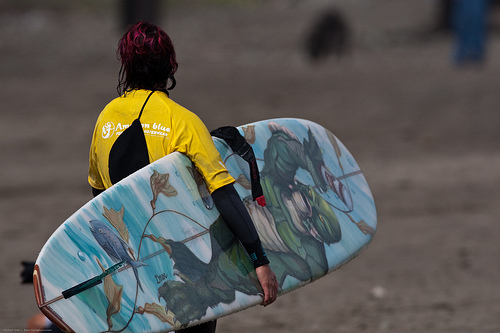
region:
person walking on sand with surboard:
[8, 20, 389, 332]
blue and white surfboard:
[9, 112, 396, 332]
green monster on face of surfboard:
[155, 122, 363, 329]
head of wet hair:
[101, 23, 193, 97]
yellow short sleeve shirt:
[80, 83, 237, 204]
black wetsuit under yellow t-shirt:
[78, 157, 273, 331]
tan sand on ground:
[5, 8, 491, 322]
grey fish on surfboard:
[83, 213, 155, 296]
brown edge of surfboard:
[22, 262, 73, 332]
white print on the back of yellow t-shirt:
[97, 113, 177, 149]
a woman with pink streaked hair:
[82, 13, 192, 101]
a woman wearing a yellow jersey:
[55, 70, 248, 217]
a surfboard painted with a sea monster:
[230, 78, 361, 318]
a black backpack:
[76, 102, 166, 184]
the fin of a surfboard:
[55, 257, 155, 314]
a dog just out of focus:
[281, 9, 397, 92]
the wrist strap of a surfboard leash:
[214, 118, 285, 203]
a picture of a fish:
[77, 215, 159, 280]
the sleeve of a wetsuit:
[209, 207, 286, 268]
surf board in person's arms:
[8, 113, 408, 297]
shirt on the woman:
[58, 90, 229, 199]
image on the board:
[128, 140, 326, 262]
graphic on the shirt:
[97, 116, 185, 146]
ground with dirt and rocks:
[16, 22, 480, 312]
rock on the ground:
[338, 278, 411, 293]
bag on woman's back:
[96, 123, 155, 173]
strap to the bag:
[130, 89, 162, 117]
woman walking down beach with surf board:
[36, 11, 369, 331]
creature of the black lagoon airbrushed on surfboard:
[40, 118, 382, 309]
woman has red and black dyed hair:
[111, 22, 180, 97]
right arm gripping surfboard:
[169, 98, 284, 311]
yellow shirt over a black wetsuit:
[85, 93, 266, 275]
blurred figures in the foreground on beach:
[297, 0, 499, 81]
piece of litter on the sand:
[370, 280, 386, 299]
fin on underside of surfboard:
[63, 263, 123, 299]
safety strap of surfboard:
[244, 120, 272, 215]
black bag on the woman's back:
[107, 90, 158, 183]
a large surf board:
[33, 114, 375, 328]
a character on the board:
[151, 123, 341, 320]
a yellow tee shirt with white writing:
[86, 86, 233, 193]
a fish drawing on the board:
[88, 220, 150, 287]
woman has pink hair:
[111, 20, 173, 89]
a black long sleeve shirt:
[211, 185, 270, 271]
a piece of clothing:
[214, 123, 269, 205]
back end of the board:
[28, 265, 70, 327]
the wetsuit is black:
[212, 188, 269, 269]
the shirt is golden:
[100, 97, 191, 174]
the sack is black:
[105, 117, 153, 187]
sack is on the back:
[104, 105, 157, 185]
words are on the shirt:
[98, 120, 172, 144]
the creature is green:
[162, 137, 333, 321]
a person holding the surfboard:
[40, 43, 368, 305]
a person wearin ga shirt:
[60, 21, 272, 237]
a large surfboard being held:
[37, 112, 376, 322]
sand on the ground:
[385, 239, 494, 316]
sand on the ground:
[327, 296, 361, 329]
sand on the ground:
[415, 187, 497, 269]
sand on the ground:
[357, 99, 457, 216]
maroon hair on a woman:
[107, 20, 184, 92]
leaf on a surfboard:
[103, 203, 134, 245]